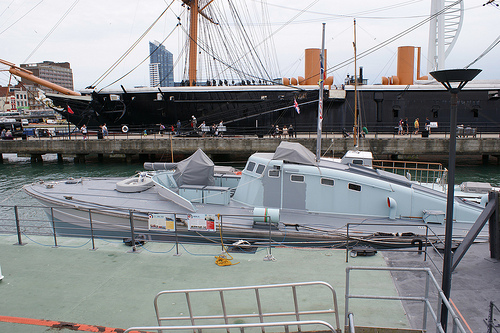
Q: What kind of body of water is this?
A: Ocean.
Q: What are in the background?
A: Tall Buildings.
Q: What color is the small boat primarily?
A: Gray.